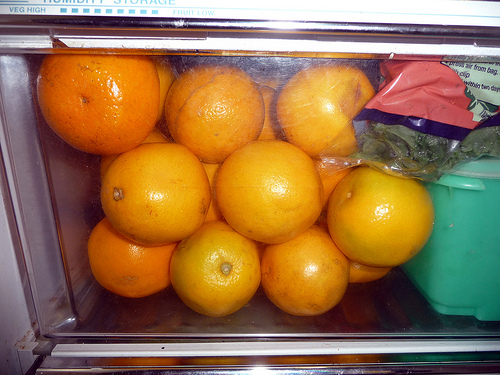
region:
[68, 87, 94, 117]
dark spot on orange fruit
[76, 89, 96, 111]
dark spot on orange fruit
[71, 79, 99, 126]
dark spot on orange fruit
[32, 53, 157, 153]
a ripe orange fruit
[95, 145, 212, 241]
a ripe orange fruit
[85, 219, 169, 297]
a ripe orange fruit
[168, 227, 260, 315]
a ripe orange fruit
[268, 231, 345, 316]
a ripe orange fruit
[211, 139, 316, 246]
a ripe orange fruit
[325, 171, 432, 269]
a ripe orange fruit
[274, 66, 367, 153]
a ripe orange fruit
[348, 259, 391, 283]
a ripe orange fruit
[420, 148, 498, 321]
a green plastic container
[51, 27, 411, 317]
bunch of oranges in package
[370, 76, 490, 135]
plastic bag is red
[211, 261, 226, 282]
light colored stem on orange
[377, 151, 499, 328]
green bowl next to oranges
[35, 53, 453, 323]
oranges in clear container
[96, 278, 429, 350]
bottom of container is dark colored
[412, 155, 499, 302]
light green bucket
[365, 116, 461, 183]
green vegetables in bag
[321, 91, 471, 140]
blue stripe on bag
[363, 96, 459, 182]
vegetable in plastic bag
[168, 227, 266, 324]
round orange orange fruit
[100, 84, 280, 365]
the oranges are visible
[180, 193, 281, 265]
the oranges are visible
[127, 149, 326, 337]
the oranges are visible